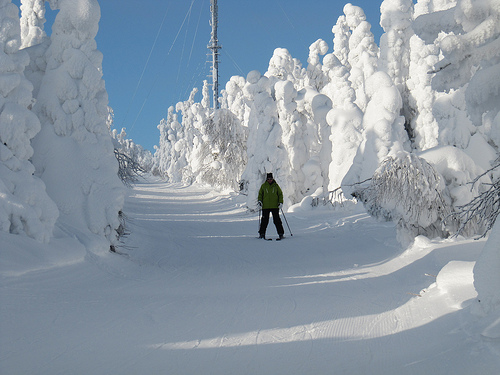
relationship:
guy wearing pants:
[255, 172, 285, 241] [259, 207, 285, 237]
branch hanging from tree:
[114, 147, 148, 188] [49, 0, 146, 257]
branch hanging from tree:
[117, 166, 123, 179] [49, 0, 146, 257]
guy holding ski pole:
[255, 172, 285, 241] [259, 203, 262, 234]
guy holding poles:
[255, 172, 285, 241] [280, 208, 293, 236]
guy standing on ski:
[255, 172, 285, 241] [256, 235, 271, 241]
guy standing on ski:
[255, 172, 285, 241] [273, 233, 286, 241]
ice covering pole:
[203, 2, 223, 109] [209, 2, 222, 114]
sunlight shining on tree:
[231, 4, 417, 203] [344, 4, 416, 200]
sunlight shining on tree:
[231, 4, 417, 203] [319, 13, 356, 69]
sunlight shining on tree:
[231, 4, 417, 203] [318, 49, 368, 201]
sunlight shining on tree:
[231, 4, 417, 203] [304, 30, 329, 89]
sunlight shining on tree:
[231, 4, 417, 203] [270, 76, 321, 206]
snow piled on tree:
[1, 1, 498, 373] [40, 1, 130, 247]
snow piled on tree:
[1, 1, 498, 373] [19, 1, 55, 101]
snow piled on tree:
[1, 1, 498, 373] [2, 1, 59, 237]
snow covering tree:
[1, 1, 498, 373] [244, 73, 290, 201]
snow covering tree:
[1, 1, 498, 373] [271, 74, 314, 196]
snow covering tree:
[1, 1, 498, 373] [262, 40, 311, 84]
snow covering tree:
[1, 1, 498, 373] [317, 45, 363, 202]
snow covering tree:
[1, 1, 498, 373] [339, 5, 412, 178]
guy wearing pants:
[255, 172, 285, 241] [254, 207, 301, 244]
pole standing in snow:
[209, 2, 222, 114] [2, 167, 492, 362]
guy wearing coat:
[255, 170, 286, 240] [258, 180, 284, 209]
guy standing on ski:
[255, 170, 286, 240] [256, 234, 273, 241]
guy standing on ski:
[255, 170, 286, 240] [275, 235, 287, 240]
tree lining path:
[240, 70, 292, 205] [2, 7, 496, 374]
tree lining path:
[317, 45, 363, 202] [2, 7, 496, 374]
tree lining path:
[376, 0, 415, 110] [2, 7, 496, 374]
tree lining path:
[34, 1, 123, 244] [2, 7, 496, 374]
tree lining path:
[2, 1, 59, 237] [2, 7, 496, 374]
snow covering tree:
[1, 1, 498, 373] [240, 69, 289, 212]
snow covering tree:
[1, 1, 498, 373] [270, 72, 320, 198]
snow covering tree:
[1, 1, 498, 373] [312, 16, 365, 201]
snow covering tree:
[1, 1, 498, 373] [330, 12, 352, 62]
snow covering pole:
[1, 1, 498, 373] [209, 2, 222, 114]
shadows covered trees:
[170, 237, 395, 339] [388, 170, 489, 228]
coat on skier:
[248, 181, 289, 211] [254, 172, 284, 242]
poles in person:
[252, 201, 297, 230] [233, 156, 321, 266]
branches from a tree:
[354, 155, 498, 230] [347, 77, 413, 208]